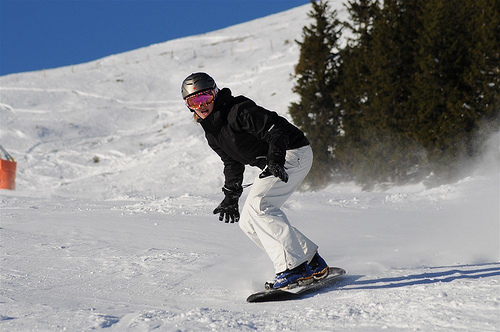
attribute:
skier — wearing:
[217, 231, 385, 328]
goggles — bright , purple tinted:
[186, 87, 218, 110]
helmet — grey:
[177, 67, 219, 102]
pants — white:
[245, 184, 285, 249]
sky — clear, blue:
[31, 11, 128, 34]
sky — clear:
[1, 1, 317, 80]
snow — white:
[51, 160, 229, 307]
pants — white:
[190, 144, 363, 279]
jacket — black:
[199, 85, 311, 188]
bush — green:
[337, 65, 460, 160]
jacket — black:
[176, 95, 313, 180]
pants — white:
[236, 142, 319, 276]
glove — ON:
[210, 179, 241, 233]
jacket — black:
[206, 107, 294, 169]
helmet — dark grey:
[177, 70, 221, 95]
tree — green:
[292, 3, 498, 181]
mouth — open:
[199, 105, 210, 115]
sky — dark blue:
[2, 3, 348, 70]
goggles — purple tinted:
[183, 81, 221, 108]